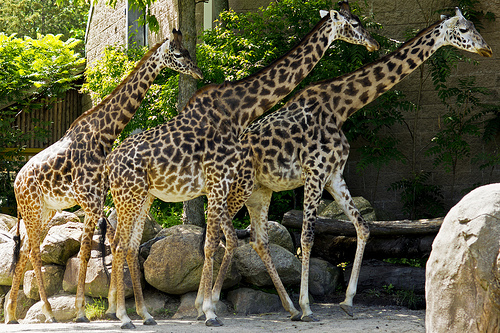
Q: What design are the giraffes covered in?
A: Spots.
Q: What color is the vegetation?
A: Green.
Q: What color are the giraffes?
A: Brown and yellow.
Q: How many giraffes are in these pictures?
A: Three.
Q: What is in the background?
A: A brick wall.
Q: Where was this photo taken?
A: At an animal exhibit.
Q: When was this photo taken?
A: Outside, during the daytime.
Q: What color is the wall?
A: Beige.